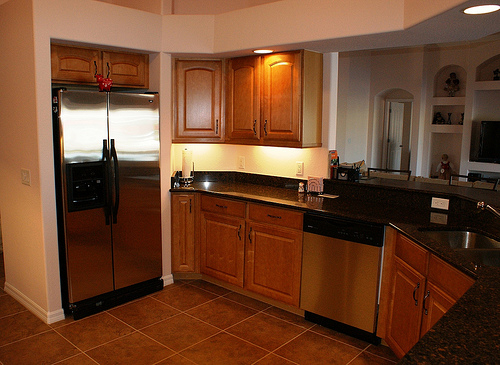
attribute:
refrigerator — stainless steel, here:
[56, 85, 158, 316]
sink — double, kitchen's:
[421, 223, 500, 253]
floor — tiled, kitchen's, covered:
[6, 287, 393, 358]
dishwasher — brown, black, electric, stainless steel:
[296, 210, 390, 344]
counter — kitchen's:
[172, 167, 499, 364]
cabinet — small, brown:
[53, 45, 100, 83]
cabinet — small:
[103, 49, 152, 82]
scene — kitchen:
[9, 3, 494, 356]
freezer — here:
[61, 86, 121, 302]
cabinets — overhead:
[171, 47, 333, 147]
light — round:
[252, 46, 274, 56]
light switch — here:
[14, 165, 34, 190]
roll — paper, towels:
[183, 145, 193, 181]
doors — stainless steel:
[55, 77, 172, 320]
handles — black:
[101, 136, 119, 229]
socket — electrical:
[427, 195, 458, 212]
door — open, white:
[383, 102, 408, 168]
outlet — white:
[236, 156, 245, 168]